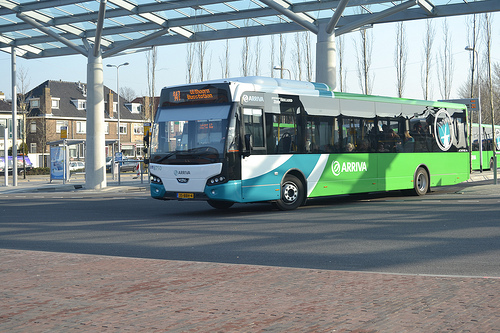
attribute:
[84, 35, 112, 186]
structure — metal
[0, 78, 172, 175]
building — brick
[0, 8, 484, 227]
shelter — bus 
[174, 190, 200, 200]
license plate — yellow, blue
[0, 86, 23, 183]
building — white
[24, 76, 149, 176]
building — brick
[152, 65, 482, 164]
bus — green and blue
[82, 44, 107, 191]
column — concrete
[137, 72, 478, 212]
bus — public transportation, light blue, green, white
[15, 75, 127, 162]
house — large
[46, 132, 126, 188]
bus stop — covered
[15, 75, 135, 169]
house — brown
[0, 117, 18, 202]
white post — white 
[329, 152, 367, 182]
company name — white 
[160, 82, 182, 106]
bus number — 41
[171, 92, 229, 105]
route — orange 